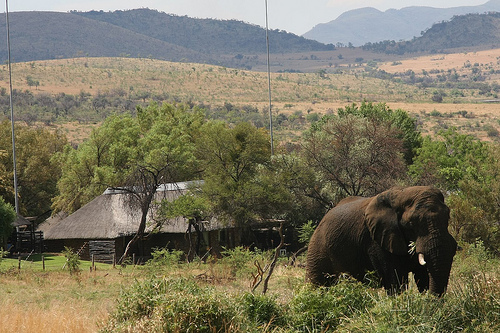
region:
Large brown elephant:
[303, 184, 458, 297]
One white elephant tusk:
[415, 251, 427, 268]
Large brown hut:
[30, 176, 251, 266]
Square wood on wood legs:
[85, 237, 117, 274]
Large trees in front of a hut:
[30, 103, 282, 263]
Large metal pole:
[3, 0, 24, 263]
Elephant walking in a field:
[305, 183, 461, 298]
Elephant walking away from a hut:
[13, 173, 460, 299]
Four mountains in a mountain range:
[1, 2, 498, 68]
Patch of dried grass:
[2, 295, 125, 331]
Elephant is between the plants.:
[295, 180, 465, 301]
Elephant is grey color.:
[297, 177, 462, 297]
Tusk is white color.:
[401, 240, 427, 280]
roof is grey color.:
[20, 181, 245, 236]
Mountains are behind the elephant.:
[6, 5, 487, 90]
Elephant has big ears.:
[287, 175, 458, 286]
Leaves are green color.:
[123, 117, 265, 170]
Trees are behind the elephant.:
[1, 113, 483, 241]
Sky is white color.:
[208, 5, 328, 32]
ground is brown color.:
[85, 54, 470, 121]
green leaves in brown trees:
[20, 129, 84, 169]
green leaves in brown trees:
[118, 122, 163, 156]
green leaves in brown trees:
[219, 111, 253, 161]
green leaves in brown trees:
[292, 128, 338, 180]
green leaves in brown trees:
[349, 107, 415, 161]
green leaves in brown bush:
[159, 293, 198, 331]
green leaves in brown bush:
[271, 298, 315, 323]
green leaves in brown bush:
[322, 275, 389, 329]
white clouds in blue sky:
[256, 5, 288, 25]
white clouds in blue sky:
[191, 5, 222, 17]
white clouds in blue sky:
[275, 3, 305, 26]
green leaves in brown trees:
[172, 106, 207, 170]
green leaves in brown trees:
[97, 145, 137, 181]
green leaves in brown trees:
[7, 152, 32, 184]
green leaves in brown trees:
[233, 159, 267, 205]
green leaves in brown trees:
[270, 175, 296, 216]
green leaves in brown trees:
[316, 140, 375, 172]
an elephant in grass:
[276, 173, 482, 320]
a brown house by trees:
[48, 160, 289, 269]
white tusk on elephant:
[411, 234, 441, 271]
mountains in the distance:
[33, 8, 450, 93]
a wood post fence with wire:
[24, 243, 254, 276]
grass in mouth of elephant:
[394, 235, 434, 285]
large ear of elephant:
[354, 186, 413, 264]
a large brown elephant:
[278, 191, 485, 326]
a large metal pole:
[3, 0, 31, 257]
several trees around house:
[43, 86, 461, 321]